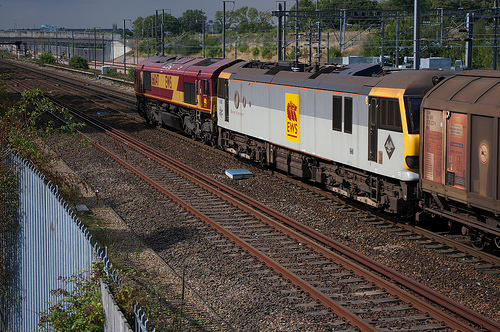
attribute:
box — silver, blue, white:
[225, 167, 253, 181]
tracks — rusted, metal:
[1, 59, 500, 331]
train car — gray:
[217, 59, 457, 221]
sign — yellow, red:
[284, 93, 300, 144]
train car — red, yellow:
[135, 54, 245, 146]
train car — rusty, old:
[415, 69, 499, 253]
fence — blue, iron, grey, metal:
[2, 150, 157, 331]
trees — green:
[133, 1, 500, 72]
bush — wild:
[68, 56, 89, 70]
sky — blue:
[1, 0, 317, 34]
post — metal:
[93, 27, 97, 68]